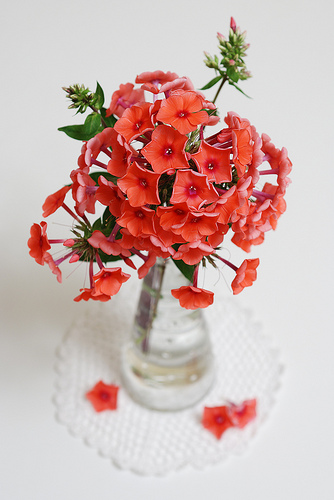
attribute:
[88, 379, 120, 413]
flower — in foreground, red, blurred, small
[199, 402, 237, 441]
flower — in foreground, red, blurred, small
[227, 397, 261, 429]
flower — in foreground, red, blurred, small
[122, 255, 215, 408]
flower vase — clear, glass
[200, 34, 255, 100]
flower — green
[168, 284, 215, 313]
flower — blooming, red, pink, orange, hanging down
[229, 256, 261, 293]
flower — blooming, small, pink, red, orange, hanging down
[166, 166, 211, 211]
flower — blooming, shaped like a star, pink, red, orange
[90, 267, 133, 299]
flower — blooming, pink, red, orange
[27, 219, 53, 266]
flower — blooming, small, pink, red, orange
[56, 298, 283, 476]
doylie — white, round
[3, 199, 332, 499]
table — white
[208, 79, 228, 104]
stem — green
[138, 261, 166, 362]
stem — green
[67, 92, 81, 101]
flower bud — small, closed, blossoming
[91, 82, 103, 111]
leaf — green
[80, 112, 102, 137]
leaf — green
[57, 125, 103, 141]
leaf — green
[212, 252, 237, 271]
strand — long